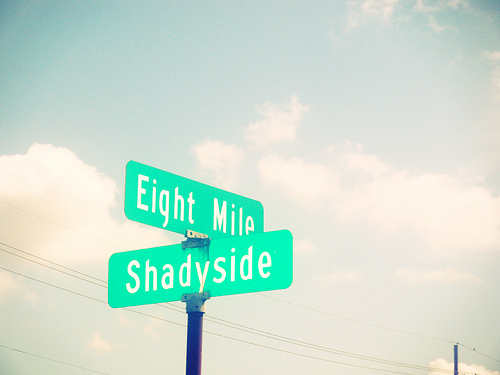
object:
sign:
[79, 160, 333, 308]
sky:
[26, 26, 472, 331]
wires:
[33, 255, 427, 373]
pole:
[180, 299, 211, 375]